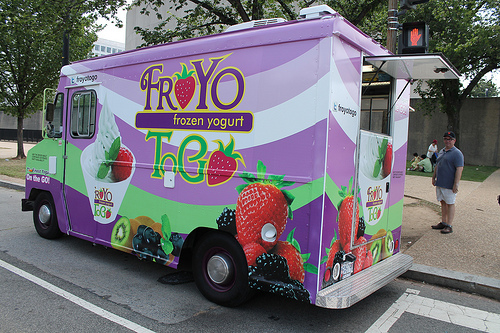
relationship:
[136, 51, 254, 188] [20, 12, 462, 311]
logo on truck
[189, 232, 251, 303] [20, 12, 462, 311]
back tire of truck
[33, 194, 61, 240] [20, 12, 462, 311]
front tire of truck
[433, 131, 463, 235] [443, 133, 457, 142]
man wearing a hat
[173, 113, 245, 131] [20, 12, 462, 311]
writing on truck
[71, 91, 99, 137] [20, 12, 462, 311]
window on truck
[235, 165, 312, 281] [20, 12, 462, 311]
strawberries painted on truck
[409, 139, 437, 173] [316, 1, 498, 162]
family group under tree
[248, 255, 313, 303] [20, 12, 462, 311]
blackberries painted on truck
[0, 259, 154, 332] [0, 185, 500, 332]
line painted on road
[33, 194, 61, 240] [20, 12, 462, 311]
front tire on truck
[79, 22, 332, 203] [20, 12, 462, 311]
shades of purple on truck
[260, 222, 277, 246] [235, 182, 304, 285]
gas filler cap in middle of strawberries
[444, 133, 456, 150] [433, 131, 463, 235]
head of man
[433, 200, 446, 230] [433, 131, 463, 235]
left foot of man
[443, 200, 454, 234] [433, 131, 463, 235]
leg of man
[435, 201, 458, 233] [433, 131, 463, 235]
feet of man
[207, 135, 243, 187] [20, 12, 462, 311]
strawberry on truck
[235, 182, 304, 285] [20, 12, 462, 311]
strawberries on truck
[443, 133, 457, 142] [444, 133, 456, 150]
hat on mans head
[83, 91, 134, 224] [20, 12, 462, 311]
froyo on truck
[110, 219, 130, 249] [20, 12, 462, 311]
kiwi on truck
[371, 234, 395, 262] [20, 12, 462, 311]
kiwis on truck